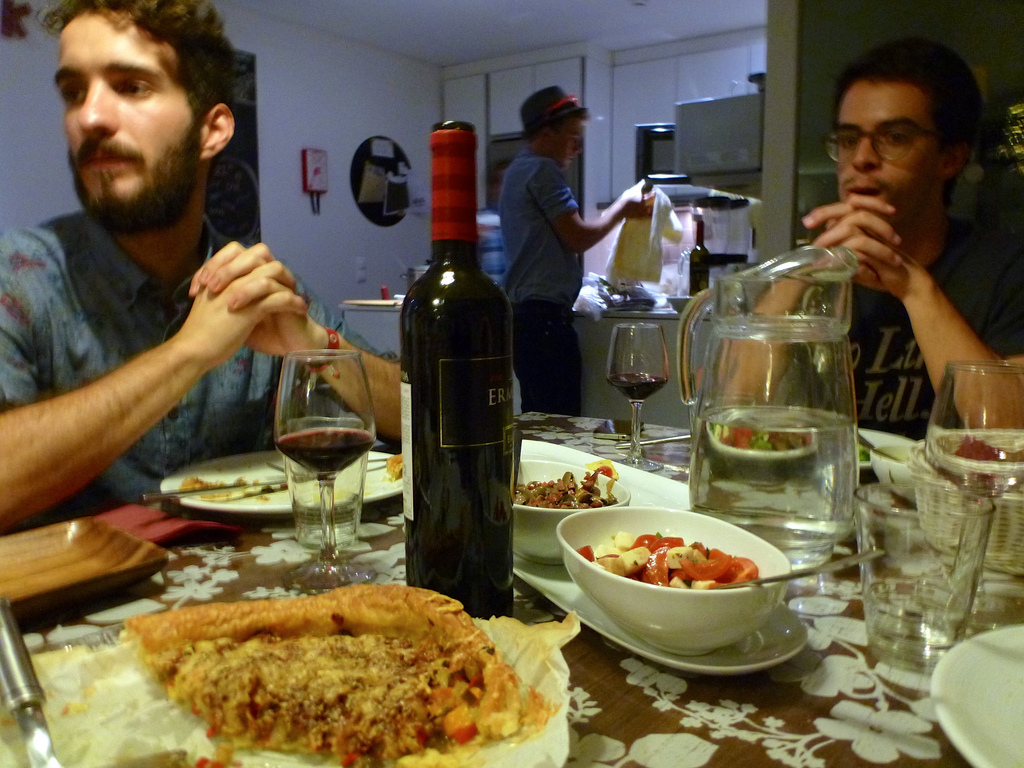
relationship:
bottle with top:
[404, 119, 500, 601] [433, 134, 488, 241]